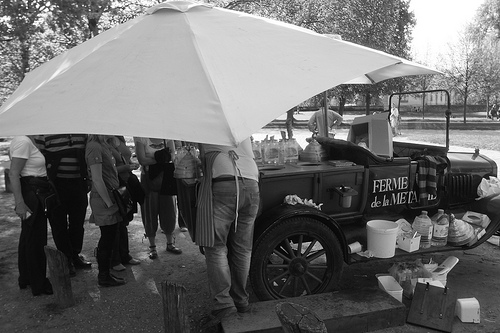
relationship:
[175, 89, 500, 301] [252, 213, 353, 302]
car has wheel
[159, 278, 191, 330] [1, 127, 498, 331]
post in ground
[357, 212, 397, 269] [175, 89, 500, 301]
bucket on car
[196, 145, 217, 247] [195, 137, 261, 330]
apron on person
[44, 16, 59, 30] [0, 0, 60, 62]
leaves on tree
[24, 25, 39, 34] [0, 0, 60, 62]
leaves on tree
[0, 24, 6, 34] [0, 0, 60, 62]
leaves on tree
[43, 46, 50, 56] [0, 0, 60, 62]
leaves on tree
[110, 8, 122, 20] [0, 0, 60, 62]
leaves on tree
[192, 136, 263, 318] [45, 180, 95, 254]
person wearing dark pants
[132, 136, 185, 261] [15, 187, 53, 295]
person wearing dark pants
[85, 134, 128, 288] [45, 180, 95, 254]
person wearing dark pants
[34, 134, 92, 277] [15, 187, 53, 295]
people wearing dark pants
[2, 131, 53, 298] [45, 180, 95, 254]
person wearing dark pants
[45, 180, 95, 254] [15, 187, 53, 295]
dark pants wearing dark pants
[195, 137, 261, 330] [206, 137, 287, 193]
person wearing shirt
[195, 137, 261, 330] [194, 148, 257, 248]
person wearing apron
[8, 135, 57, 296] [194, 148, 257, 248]
person wearing apron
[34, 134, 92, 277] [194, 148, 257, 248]
people wearing apron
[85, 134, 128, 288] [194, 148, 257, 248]
person wearing apron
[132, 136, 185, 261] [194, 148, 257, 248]
person wearing apron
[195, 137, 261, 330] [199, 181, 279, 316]
person wearing jeans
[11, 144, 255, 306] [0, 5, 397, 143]
people under umbrella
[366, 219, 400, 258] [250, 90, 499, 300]
bucket on car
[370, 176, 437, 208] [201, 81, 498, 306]
name on car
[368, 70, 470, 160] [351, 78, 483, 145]
dark frame on windscreen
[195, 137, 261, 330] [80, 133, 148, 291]
person wearing dress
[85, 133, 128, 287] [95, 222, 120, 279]
person wearing pants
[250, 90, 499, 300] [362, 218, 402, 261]
car has bucket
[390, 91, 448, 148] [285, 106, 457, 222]
windscreen mounted on car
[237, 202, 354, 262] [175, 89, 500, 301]
front fender mounted on car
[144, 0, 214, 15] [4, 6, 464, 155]
top sewn on umbrella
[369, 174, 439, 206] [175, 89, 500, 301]
name painted on car